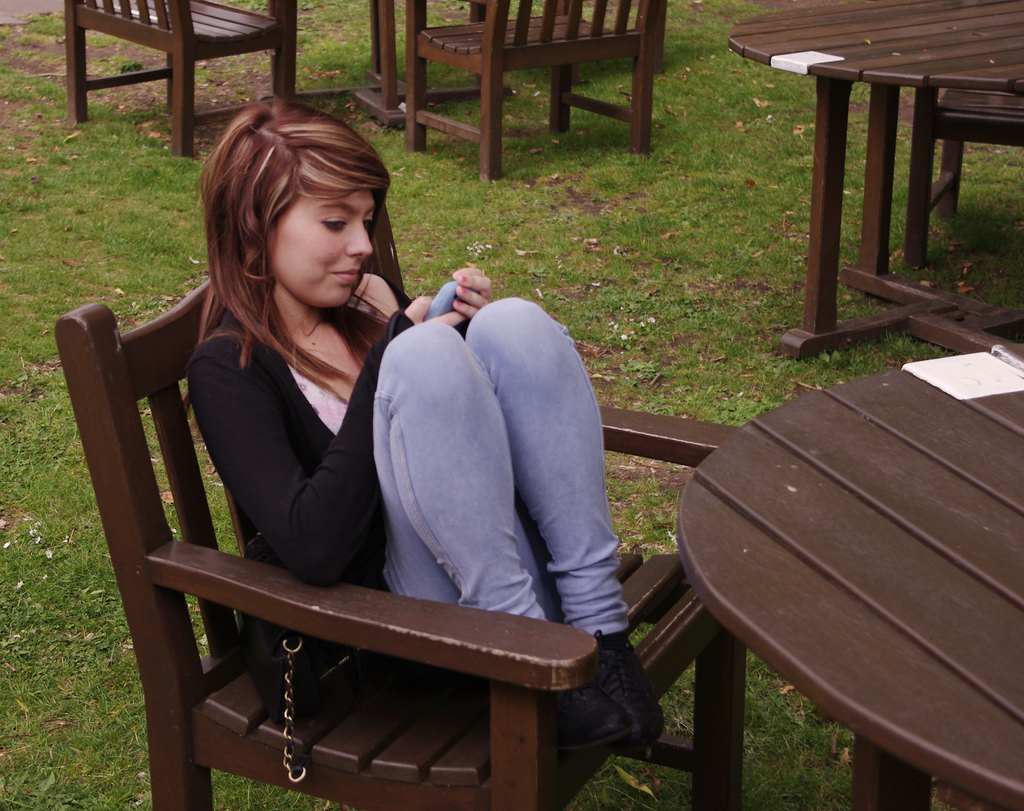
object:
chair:
[54, 279, 746, 811]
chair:
[63, 0, 296, 157]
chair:
[406, 0, 668, 183]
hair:
[169, 84, 404, 430]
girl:
[173, 82, 663, 750]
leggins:
[372, 321, 547, 621]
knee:
[377, 322, 497, 414]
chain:
[284, 638, 308, 785]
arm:
[187, 336, 381, 587]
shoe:
[558, 629, 637, 751]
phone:
[424, 281, 481, 332]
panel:
[150, 382, 241, 658]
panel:
[803, 74, 855, 334]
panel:
[599, 406, 742, 468]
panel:
[622, 554, 685, 636]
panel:
[632, 588, 723, 704]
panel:
[490, 680, 558, 811]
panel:
[145, 539, 599, 691]